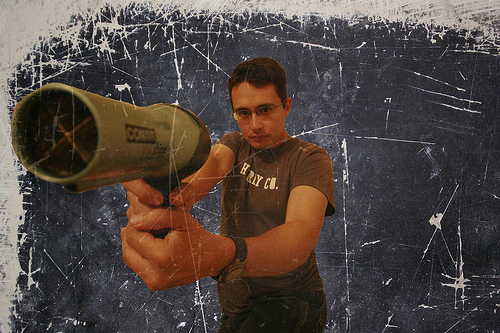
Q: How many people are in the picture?
A: One.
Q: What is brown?
A: The shirt.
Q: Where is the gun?
A: In his hands.